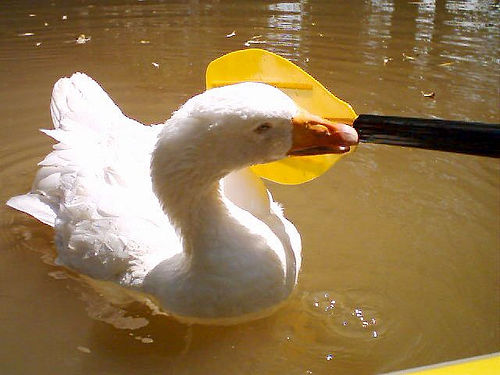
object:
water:
[1, 1, 155, 72]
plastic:
[204, 49, 358, 186]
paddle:
[204, 48, 500, 186]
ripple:
[307, 290, 429, 360]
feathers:
[109, 221, 163, 262]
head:
[166, 82, 359, 170]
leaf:
[139, 39, 151, 45]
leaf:
[75, 33, 88, 45]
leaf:
[16, 27, 36, 39]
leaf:
[151, 61, 159, 68]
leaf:
[61, 13, 71, 24]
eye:
[252, 122, 272, 135]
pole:
[354, 113, 500, 159]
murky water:
[351, 178, 480, 297]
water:
[299, 194, 427, 324]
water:
[350, 206, 455, 264]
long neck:
[150, 144, 237, 251]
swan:
[7, 72, 358, 326]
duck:
[4, 71, 359, 326]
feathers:
[95, 158, 136, 207]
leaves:
[17, 30, 37, 38]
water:
[139, 16, 250, 45]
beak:
[285, 114, 358, 156]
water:
[367, 14, 446, 95]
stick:
[351, 113, 500, 159]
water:
[0, 107, 35, 192]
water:
[0, 277, 116, 374]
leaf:
[379, 55, 390, 63]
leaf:
[418, 89, 434, 97]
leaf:
[439, 62, 455, 69]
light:
[272, 11, 299, 27]